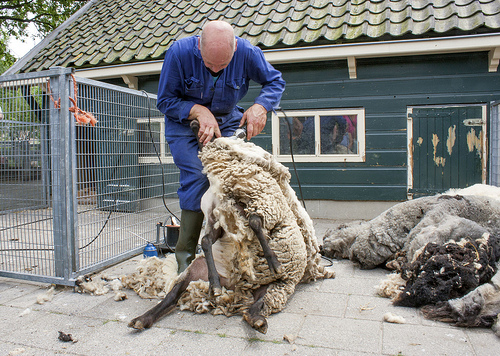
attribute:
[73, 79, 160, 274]
fence — metal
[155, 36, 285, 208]
suit — blue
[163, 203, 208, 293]
boots — green